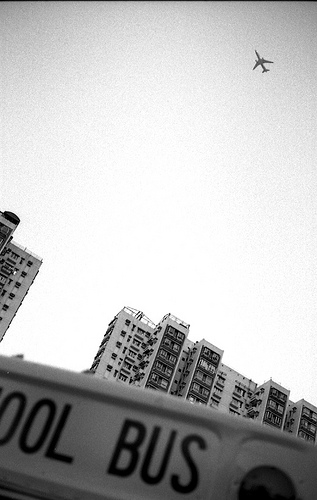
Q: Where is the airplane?
A: In the sky.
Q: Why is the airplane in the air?
A: Flying.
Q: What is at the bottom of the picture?
A: School bus.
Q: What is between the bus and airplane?
A: Buildings.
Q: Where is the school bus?
A: At the bottom of the picture.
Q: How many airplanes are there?
A: One.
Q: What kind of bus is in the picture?
A: School bus.